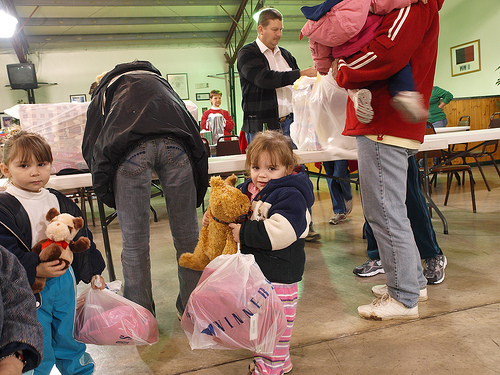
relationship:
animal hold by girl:
[38, 210, 90, 260] [0, 130, 104, 288]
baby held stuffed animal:
[201, 129, 315, 375] [177, 173, 252, 272]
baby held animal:
[0, 129, 105, 375] [30, 207, 91, 295]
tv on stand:
[5, 61, 38, 85] [5, 83, 44, 100]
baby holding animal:
[0, 129, 105, 375] [30, 207, 91, 295]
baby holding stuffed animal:
[201, 129, 315, 375] [183, 174, 237, 268]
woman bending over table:
[77, 56, 220, 320] [3, 141, 453, 204]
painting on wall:
[448, 38, 483, 78] [433, 2, 499, 95]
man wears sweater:
[235, 10, 299, 135] [241, 38, 298, 121]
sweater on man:
[241, 38, 298, 121] [235, 10, 299, 135]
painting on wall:
[449, 39, 482, 78] [438, 1, 498, 121]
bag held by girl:
[179, 253, 282, 360] [219, 134, 316, 374]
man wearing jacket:
[336, 0, 440, 318] [348, 1, 426, 133]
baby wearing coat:
[201, 129, 315, 375] [236, 169, 314, 278]